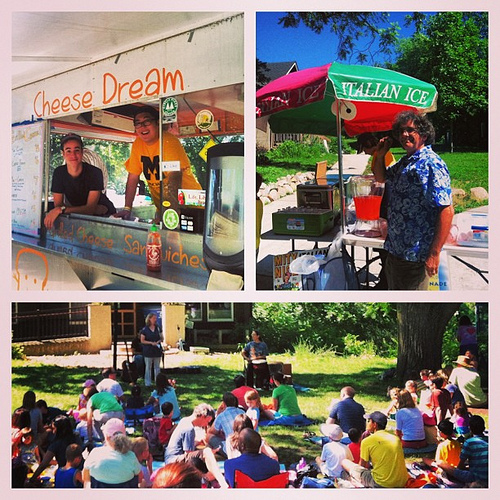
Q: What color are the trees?
A: Green.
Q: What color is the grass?
A: Green.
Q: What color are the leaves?
A: Green.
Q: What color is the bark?
A: Brown.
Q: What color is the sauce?
A: Red.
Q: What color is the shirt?
A: Blue.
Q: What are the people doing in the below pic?
A: Sitting.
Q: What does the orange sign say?
A: Cheese dream.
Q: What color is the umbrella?
A: Red and green.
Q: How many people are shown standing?
A: Five.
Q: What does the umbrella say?
A: Italian Ice.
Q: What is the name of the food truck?
A: Cheese Dream.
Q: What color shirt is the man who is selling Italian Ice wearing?
A: Blue and white.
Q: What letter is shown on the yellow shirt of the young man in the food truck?
A: M.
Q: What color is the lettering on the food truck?
A: Orange.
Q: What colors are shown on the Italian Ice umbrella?
A: Red and Green.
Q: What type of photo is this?
A: A collage.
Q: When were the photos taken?
A: During the day.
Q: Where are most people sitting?
A: On the ground.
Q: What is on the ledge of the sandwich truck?
A: Hot sauce.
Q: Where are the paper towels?
A: Under the umbrella.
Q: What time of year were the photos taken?
A: Summertime.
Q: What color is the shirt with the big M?
A: Yellow.